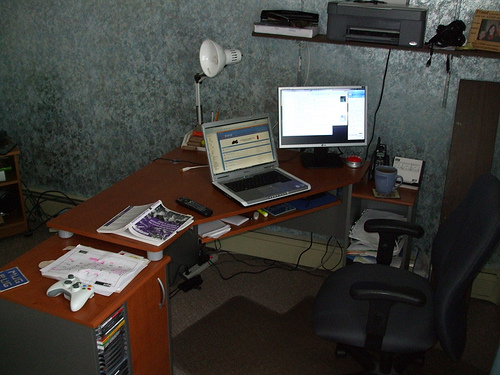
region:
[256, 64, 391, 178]
silver monitor on table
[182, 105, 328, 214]
silver lap top on table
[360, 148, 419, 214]
blue coffee cup on table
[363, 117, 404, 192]
black phone on table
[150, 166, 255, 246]
black remote on table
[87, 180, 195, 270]
book on table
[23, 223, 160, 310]
papers on table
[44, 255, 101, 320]
white video game controller on table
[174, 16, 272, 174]
white table lamp on table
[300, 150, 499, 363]
swivel chair in office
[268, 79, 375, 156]
a screen over a desk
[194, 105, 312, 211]
a laptop over a desk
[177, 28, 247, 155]
a white lamp on a desk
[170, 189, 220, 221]
a black remote control on a desk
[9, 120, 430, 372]
the desk is color brown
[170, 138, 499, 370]
a chair in front a desk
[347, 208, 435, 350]
armrests of chair are black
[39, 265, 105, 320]
a white game control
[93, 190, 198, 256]
a book on a table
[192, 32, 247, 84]
a bulb in a lamp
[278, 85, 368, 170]
A computer monitor with silver trim.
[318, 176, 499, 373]
Black computer chair with arm rests.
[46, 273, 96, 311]
White X-Box 360 controller.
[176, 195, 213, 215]
A black remote on a wooden desk.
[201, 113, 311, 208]
A silver laptop with black keys.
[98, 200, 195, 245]
An open book laid face down.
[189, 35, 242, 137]
A white desk lamp.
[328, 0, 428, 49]
A black printer on a mantle.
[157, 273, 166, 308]
The silver handle of a desk door.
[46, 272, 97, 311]
White and grey game controller.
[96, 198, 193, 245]
A paperback book , open and face down.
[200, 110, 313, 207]
A laptop computer open to a website.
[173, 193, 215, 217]
A TV remote control.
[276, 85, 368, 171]
A computer monitor, with windows open.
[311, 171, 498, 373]
A desk chair with arm rests.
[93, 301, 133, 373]
A stack of CD's or DVD's.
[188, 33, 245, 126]
A white desk lamp.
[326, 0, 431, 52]
A gray computer printer.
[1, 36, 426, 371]
A wooden and gray metal computer desk.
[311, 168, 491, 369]
a black office chair is in the room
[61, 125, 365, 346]
a corner desk is in th room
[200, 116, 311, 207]
an open laptop is on the desk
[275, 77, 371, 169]
a monitor is on the side of the desk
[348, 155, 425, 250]
a coffe cupis on the side desk extension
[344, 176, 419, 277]
papers are stacked on a shelf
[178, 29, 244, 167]
a white lamp is on the desk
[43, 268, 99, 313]
a game controller is sitting near a file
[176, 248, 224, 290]
a surge protector is on the floor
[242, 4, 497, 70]
a shelf is on the wall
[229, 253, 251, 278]
black cords under the desk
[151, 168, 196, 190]
a wooden desk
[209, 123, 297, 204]
a laptop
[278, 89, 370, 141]
a computer monitor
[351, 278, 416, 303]
a armrest on the chair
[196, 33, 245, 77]
a light on the desk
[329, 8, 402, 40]
a printer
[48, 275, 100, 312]
a white controller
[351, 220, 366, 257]
a pile of papers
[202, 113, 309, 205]
laptop on wooden desk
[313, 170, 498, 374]
chair next to wooden desk